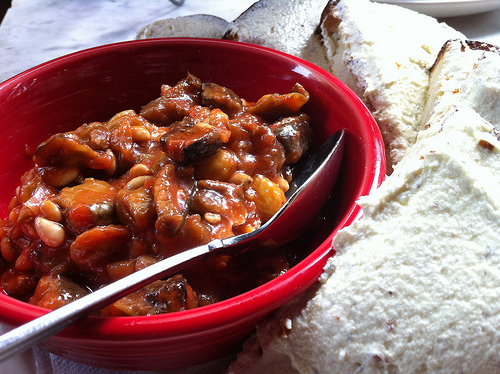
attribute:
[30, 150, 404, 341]
spoon — silver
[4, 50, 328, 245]
bowl — round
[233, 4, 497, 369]
bread — toasted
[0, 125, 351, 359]
spoon — silver, metal, large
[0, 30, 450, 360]
bowl — red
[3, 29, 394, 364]
bowl — red, deep